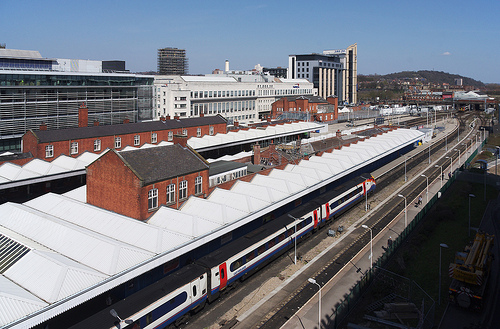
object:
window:
[67, 135, 85, 155]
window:
[148, 185, 158, 207]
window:
[166, 182, 175, 202]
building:
[285, 52, 343, 100]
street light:
[304, 273, 324, 325]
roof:
[110, 142, 210, 185]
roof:
[29, 113, 229, 143]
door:
[215, 257, 232, 287]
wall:
[84, 153, 141, 220]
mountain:
[367, 65, 473, 102]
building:
[158, 46, 185, 71]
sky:
[221, 9, 313, 44]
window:
[93, 138, 100, 151]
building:
[20, 114, 230, 165]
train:
[62, 165, 397, 327]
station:
[28, 130, 498, 325]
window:
[193, 174, 203, 192]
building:
[78, 134, 208, 219]